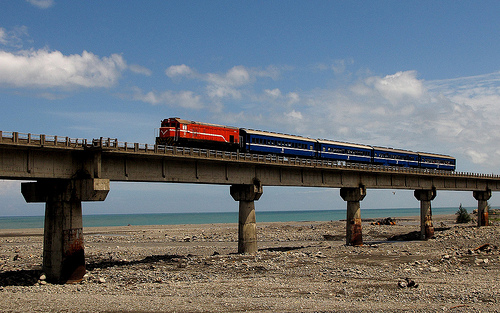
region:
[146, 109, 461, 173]
train on bridge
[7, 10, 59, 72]
white clouds in blue sky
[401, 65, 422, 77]
white clouds in blue sky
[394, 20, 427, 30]
white clouds in blue sky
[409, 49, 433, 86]
white clouds in blue sky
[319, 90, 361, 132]
white clouds in blue sky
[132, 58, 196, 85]
white clouds in blue sky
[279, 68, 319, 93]
white clouds in blue sky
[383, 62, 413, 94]
white clouds in blue sky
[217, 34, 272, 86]
white clouds in blue sky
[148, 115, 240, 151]
a red train car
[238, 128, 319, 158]
a blue train car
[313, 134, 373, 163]
a blue train car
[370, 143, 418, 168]
a blue train car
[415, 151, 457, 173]
a blue train car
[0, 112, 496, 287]
an elevated set of train tracks near an ocean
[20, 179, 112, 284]
a concrete support for train tracks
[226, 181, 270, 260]
a concrete support for train tracks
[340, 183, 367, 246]
a concrete support for train tracks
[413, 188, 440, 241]
a concrete support for train tracks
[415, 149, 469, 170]
blue colored caboose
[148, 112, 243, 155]
red colored part of train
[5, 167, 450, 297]
bridge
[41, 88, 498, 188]
red and blue train on railroad track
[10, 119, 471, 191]
train on bridge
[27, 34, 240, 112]
white clouds in blue sky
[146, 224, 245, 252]
sand and gravel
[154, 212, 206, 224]
blue body of water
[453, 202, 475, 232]
green shrub in rocky area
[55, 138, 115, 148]
railing on bridge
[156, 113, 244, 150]
a red train engine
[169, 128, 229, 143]
a white stripe on a train engine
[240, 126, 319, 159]
a blue passenger car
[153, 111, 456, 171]
a train on a bridge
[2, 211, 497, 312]
a rocky beach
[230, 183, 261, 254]
a concrete pillar supporting a bridge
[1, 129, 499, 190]
a concrete bridge over a beach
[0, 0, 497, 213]
a blue cloudy sky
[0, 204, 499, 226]
blue water beyond the beach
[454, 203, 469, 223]
a green tree on the beach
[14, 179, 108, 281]
a concrete support for a train track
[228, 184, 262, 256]
a concrete support for a train track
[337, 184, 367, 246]
a concrete support for a train track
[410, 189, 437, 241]
a concrete support for a train track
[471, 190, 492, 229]
a concrete support for a train track